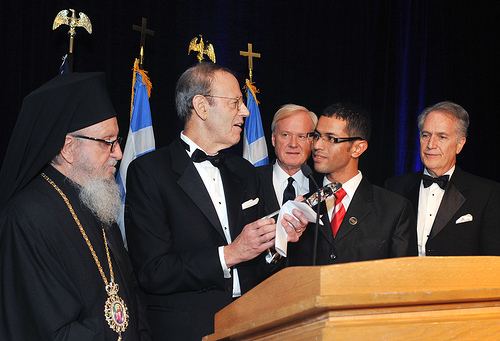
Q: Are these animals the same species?
A: Yes, all the animals are eagles.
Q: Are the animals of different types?
A: No, all the animals are eagles.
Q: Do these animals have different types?
A: No, all the animals are eagles.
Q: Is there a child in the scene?
A: No, there are no children.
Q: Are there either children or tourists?
A: No, there are no children or tourists.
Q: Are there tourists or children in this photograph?
A: No, there are no children or tourists.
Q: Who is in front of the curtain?
A: The man is in front of the curtain.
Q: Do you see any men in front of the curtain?
A: Yes, there is a man in front of the curtain.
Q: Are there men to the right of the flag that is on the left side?
A: Yes, there is a man to the right of the flag.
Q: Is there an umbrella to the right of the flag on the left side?
A: No, there is a man to the right of the flag.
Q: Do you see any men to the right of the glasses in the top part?
A: Yes, there is a man to the right of the glasses.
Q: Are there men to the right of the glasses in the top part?
A: Yes, there is a man to the right of the glasses.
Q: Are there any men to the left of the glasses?
A: No, the man is to the right of the glasses.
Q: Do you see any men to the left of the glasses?
A: No, the man is to the right of the glasses.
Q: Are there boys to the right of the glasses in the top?
A: No, there is a man to the right of the glasses.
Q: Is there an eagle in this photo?
A: Yes, there is an eagle.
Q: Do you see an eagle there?
A: Yes, there is an eagle.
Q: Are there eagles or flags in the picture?
A: Yes, there is an eagle.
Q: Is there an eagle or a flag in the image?
A: Yes, there is an eagle.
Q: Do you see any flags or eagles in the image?
A: Yes, there is an eagle.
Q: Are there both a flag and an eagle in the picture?
A: Yes, there are both an eagle and a flag.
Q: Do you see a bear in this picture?
A: No, there are no bears.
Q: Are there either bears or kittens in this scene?
A: No, there are no bears or kittens.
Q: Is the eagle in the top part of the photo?
A: Yes, the eagle is in the top of the image.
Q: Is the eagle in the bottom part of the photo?
A: No, the eagle is in the top of the image.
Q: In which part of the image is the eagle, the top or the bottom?
A: The eagle is in the top of the image.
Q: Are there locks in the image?
A: No, there are no locks.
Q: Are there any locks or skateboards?
A: No, there are no locks or skateboards.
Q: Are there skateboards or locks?
A: No, there are no locks or skateboards.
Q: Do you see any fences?
A: No, there are no fences.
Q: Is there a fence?
A: No, there are no fences.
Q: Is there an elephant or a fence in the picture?
A: No, there are no fences or elephants.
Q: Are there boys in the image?
A: No, there are no boys.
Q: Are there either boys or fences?
A: No, there are no boys or fences.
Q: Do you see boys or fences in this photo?
A: No, there are no boys or fences.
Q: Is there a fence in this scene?
A: No, there are no fences.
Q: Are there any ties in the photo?
A: Yes, there is a tie.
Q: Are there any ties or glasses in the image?
A: Yes, there is a tie.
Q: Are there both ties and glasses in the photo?
A: Yes, there are both a tie and glasses.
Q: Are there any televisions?
A: No, there are no televisions.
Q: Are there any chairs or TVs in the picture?
A: No, there are no TVs or chairs.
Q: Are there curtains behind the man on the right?
A: Yes, there is a curtain behind the man.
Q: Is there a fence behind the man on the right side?
A: No, there is a curtain behind the man.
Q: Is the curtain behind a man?
A: Yes, the curtain is behind a man.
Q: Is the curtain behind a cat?
A: No, the curtain is behind a man.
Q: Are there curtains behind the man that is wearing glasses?
A: Yes, there is a curtain behind the man.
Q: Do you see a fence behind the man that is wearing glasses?
A: No, there is a curtain behind the man.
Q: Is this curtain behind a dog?
A: No, the curtain is behind a man.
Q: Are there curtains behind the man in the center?
A: Yes, there is a curtain behind the man.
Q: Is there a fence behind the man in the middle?
A: No, there is a curtain behind the man.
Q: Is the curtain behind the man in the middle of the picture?
A: Yes, the curtain is behind the man.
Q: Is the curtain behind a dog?
A: No, the curtain is behind the man.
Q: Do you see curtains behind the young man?
A: Yes, there is a curtain behind the man.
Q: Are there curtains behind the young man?
A: Yes, there is a curtain behind the man.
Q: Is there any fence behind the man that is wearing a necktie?
A: No, there is a curtain behind the man.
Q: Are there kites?
A: No, there are no kites.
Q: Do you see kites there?
A: No, there are no kites.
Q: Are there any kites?
A: No, there are no kites.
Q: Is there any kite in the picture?
A: No, there are no kites.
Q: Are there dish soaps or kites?
A: No, there are no kites or dish soaps.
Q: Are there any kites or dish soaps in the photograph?
A: No, there are no kites or dish soaps.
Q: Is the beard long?
A: Yes, the beard is long.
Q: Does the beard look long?
A: Yes, the beard is long.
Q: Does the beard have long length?
A: Yes, the beard is long.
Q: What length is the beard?
A: The beard is long.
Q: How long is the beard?
A: The beard is long.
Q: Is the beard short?
A: No, the beard is long.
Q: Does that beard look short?
A: No, the beard is long.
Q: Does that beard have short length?
A: No, the beard is long.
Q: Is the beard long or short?
A: The beard is long.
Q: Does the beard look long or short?
A: The beard is long.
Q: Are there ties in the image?
A: Yes, there is a tie.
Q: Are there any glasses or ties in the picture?
A: Yes, there is a tie.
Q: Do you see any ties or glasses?
A: Yes, there is a tie.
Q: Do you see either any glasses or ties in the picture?
A: Yes, there is a tie.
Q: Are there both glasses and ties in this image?
A: Yes, there are both a tie and glasses.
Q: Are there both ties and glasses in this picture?
A: Yes, there are both a tie and glasses.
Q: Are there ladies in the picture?
A: No, there are no ladies.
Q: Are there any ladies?
A: No, there are no ladies.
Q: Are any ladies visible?
A: No, there are no ladies.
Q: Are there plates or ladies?
A: No, there are no ladies or plates.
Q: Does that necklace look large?
A: Yes, the necklace is large.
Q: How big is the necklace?
A: The necklace is large.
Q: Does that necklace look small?
A: No, the necklace is large.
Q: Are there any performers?
A: No, there are no performers.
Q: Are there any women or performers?
A: No, there are no performers or women.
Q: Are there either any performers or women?
A: No, there are no performers or women.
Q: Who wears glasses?
A: The man wears glasses.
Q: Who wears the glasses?
A: The man wears glasses.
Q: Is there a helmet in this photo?
A: No, there are no helmets.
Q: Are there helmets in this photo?
A: No, there are no helmets.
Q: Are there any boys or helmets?
A: No, there are no helmets or boys.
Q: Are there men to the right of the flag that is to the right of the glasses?
A: Yes, there is a man to the right of the flag.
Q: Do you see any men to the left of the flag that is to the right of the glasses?
A: No, the man is to the right of the flag.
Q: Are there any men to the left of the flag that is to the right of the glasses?
A: No, the man is to the right of the flag.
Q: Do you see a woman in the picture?
A: No, there are no women.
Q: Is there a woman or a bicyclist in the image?
A: No, there are no women or cyclists.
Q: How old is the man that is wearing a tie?
A: The man is young.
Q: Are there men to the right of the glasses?
A: Yes, there is a man to the right of the glasses.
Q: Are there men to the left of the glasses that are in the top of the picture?
A: No, the man is to the right of the glasses.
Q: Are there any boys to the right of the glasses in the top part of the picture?
A: No, there is a man to the right of the glasses.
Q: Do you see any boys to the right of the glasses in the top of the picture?
A: No, there is a man to the right of the glasses.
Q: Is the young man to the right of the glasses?
A: Yes, the man is to the right of the glasses.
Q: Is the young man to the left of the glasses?
A: No, the man is to the right of the glasses.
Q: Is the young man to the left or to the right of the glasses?
A: The man is to the right of the glasses.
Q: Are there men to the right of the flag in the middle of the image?
A: Yes, there is a man to the right of the flag.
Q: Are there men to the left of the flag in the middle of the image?
A: No, the man is to the right of the flag.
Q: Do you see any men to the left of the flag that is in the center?
A: No, the man is to the right of the flag.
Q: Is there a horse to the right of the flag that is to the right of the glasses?
A: No, there is a man to the right of the flag.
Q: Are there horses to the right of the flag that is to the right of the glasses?
A: No, there is a man to the right of the flag.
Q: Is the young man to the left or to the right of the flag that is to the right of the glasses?
A: The man is to the right of the flag.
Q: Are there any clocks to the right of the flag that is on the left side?
A: No, there is a man to the right of the flag.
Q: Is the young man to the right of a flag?
A: Yes, the man is to the right of a flag.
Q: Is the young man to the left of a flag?
A: No, the man is to the right of a flag.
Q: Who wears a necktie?
A: The man wears a necktie.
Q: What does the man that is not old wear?
A: The man wears a necktie.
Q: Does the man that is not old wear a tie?
A: Yes, the man wears a tie.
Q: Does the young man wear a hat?
A: No, the man wears a tie.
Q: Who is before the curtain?
A: The man is in front of the curtain.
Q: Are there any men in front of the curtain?
A: Yes, there is a man in front of the curtain.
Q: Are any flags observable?
A: Yes, there is a flag.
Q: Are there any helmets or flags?
A: Yes, there is a flag.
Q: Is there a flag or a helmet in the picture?
A: Yes, there is a flag.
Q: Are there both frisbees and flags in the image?
A: No, there is a flag but no frisbees.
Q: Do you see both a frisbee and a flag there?
A: No, there is a flag but no frisbees.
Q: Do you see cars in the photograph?
A: No, there are no cars.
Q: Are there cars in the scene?
A: No, there are no cars.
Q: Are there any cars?
A: No, there are no cars.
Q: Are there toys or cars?
A: No, there are no cars or toys.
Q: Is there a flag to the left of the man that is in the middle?
A: Yes, there is a flag to the left of the man.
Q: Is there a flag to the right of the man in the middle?
A: No, the flag is to the left of the man.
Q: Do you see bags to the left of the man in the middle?
A: No, there is a flag to the left of the man.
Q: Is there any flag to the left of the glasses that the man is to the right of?
A: Yes, there is a flag to the left of the glasses.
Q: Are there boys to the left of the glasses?
A: No, there is a flag to the left of the glasses.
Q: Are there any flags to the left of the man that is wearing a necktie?
A: Yes, there is a flag to the left of the man.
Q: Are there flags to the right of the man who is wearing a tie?
A: No, the flag is to the left of the man.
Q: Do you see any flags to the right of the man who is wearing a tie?
A: No, the flag is to the left of the man.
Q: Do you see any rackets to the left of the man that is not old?
A: No, there is a flag to the left of the man.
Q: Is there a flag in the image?
A: Yes, there is a flag.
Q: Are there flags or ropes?
A: Yes, there is a flag.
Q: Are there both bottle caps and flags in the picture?
A: No, there is a flag but no bottle caps.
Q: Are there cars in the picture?
A: No, there are no cars.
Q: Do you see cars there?
A: No, there are no cars.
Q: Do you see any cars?
A: No, there are no cars.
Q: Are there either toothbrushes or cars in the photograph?
A: No, there are no cars or toothbrushes.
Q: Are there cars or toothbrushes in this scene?
A: No, there are no cars or toothbrushes.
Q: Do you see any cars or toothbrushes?
A: No, there are no cars or toothbrushes.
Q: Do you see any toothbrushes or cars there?
A: No, there are no cars or toothbrushes.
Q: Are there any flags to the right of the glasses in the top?
A: Yes, there is a flag to the right of the glasses.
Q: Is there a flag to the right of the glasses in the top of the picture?
A: Yes, there is a flag to the right of the glasses.